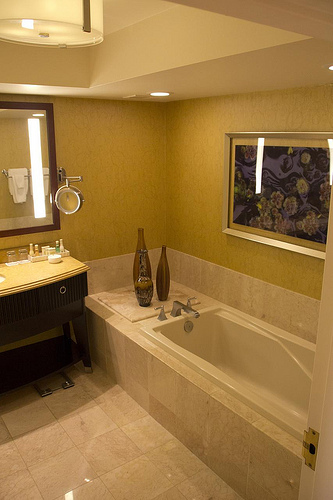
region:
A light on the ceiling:
[150, 85, 173, 96]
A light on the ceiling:
[319, 58, 332, 74]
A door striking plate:
[298, 421, 319, 473]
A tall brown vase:
[155, 240, 174, 298]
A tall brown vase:
[132, 245, 153, 308]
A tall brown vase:
[129, 223, 155, 287]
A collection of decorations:
[122, 218, 177, 307]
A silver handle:
[57, 282, 66, 292]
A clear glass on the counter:
[4, 247, 17, 267]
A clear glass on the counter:
[16, 245, 27, 262]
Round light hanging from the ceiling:
[0, 2, 105, 49]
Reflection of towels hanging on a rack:
[2, 165, 31, 205]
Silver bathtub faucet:
[151, 296, 207, 332]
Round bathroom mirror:
[54, 181, 84, 214]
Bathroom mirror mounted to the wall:
[54, 163, 87, 216]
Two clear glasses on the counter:
[3, 247, 29, 264]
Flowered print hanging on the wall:
[222, 128, 330, 260]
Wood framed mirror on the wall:
[0, 98, 63, 238]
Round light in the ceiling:
[146, 89, 172, 98]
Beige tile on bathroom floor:
[22, 409, 138, 488]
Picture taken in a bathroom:
[5, 6, 326, 498]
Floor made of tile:
[6, 384, 183, 497]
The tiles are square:
[6, 400, 186, 498]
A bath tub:
[163, 291, 322, 422]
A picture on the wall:
[202, 114, 330, 265]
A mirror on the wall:
[3, 100, 61, 227]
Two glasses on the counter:
[0, 243, 30, 268]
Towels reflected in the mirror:
[6, 157, 31, 208]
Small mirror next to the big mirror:
[56, 170, 85, 214]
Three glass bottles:
[126, 222, 177, 301]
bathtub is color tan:
[141, 292, 321, 448]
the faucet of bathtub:
[166, 300, 201, 329]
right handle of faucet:
[183, 290, 199, 305]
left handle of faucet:
[146, 301, 172, 325]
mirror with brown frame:
[0, 96, 62, 237]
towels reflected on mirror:
[1, 162, 51, 206]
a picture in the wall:
[217, 131, 328, 259]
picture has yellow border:
[217, 125, 329, 252]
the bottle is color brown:
[153, 241, 179, 301]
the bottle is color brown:
[127, 221, 150, 274]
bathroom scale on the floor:
[33, 369, 75, 397]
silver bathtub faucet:
[153, 296, 201, 321]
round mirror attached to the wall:
[54, 168, 84, 213]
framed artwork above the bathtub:
[219, 128, 327, 371]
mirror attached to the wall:
[0, 94, 57, 241]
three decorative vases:
[129, 223, 169, 308]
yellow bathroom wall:
[88, 101, 216, 227]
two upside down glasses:
[5, 248, 27, 267]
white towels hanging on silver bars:
[2, 162, 34, 208]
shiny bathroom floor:
[4, 421, 154, 494]